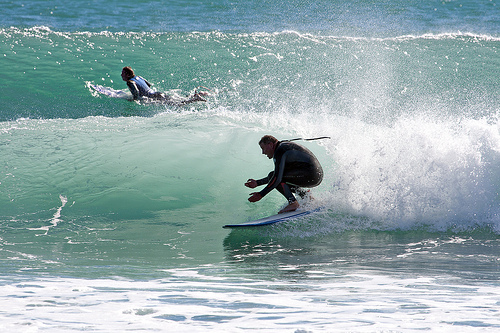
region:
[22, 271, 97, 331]
Small ripples in the water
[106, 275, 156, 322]
Small ripples in the water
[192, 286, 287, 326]
Small ripples in the water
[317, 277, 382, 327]
Small ripples in the water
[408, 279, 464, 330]
Small ripples in the water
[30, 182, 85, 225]
Small ripples in the water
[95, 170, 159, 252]
Small ripples in the water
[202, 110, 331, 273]
Man in the water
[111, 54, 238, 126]
Man in the water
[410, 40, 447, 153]
Small ripples in the water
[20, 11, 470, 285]
surfers on a beach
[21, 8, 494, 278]
the waves are wild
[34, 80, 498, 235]
this wave is wild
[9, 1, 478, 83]
this wave is forming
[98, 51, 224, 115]
this person is preparing to take a wave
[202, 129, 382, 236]
he is riding the wave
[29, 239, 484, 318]
calm and cool water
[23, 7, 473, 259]
the sun is shining down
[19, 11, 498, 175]
a lot of waves in the water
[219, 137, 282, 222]
this surfer has his arms extended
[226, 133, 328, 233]
the man is sufing on the water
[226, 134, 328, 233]
the man is riding a wave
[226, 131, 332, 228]
the man is on a surfboard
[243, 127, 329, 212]
the man is bending down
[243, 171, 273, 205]
the man has his hands extended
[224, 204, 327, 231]
the surfboard is on the water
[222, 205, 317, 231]
the surfboard is riding a wave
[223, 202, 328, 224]
the surfboard is blue in color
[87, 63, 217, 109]
the surfer is laying on the surfboard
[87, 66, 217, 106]
the surfter is moving across the wave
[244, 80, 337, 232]
man kneeling down on board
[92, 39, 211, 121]
surfer on board in water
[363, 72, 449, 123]
water spraying up from wave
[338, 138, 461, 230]
white water in crashing wave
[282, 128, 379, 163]
rope tied to surfer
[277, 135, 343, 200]
black wet suit on surfer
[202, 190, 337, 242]
blue surf board in water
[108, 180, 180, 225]
green water in wave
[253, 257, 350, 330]
white foam in green water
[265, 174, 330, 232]
bear feet on surf board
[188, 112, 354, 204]
This is a surfer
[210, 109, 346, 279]
This is a man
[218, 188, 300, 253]
This is a surfboard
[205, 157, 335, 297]
The board is blue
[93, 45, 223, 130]
This is another man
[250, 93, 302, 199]
This is a wetsuit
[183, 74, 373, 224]
The wetsuit is black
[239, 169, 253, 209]
These are two hands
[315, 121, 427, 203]
The waves are white